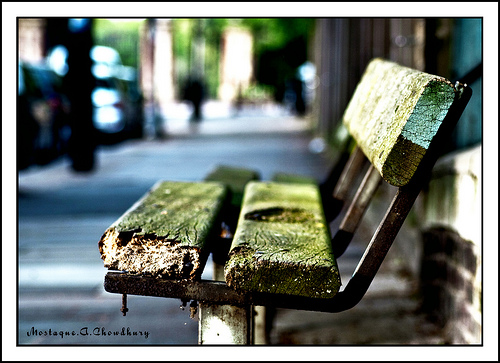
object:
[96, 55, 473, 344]
bench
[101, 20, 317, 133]
sun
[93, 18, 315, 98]
tree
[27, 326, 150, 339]
name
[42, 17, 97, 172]
pole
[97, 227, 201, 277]
edge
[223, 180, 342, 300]
wood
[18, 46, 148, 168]
car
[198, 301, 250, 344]
leg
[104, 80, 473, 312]
brace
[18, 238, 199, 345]
lower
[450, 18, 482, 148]
window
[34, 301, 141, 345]
bottom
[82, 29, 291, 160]
background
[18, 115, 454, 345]
ground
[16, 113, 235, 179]
curb